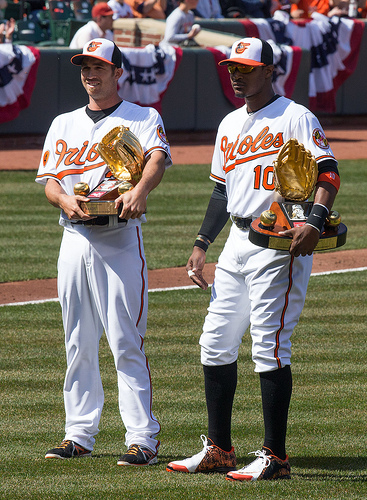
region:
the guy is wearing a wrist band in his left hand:
[164, 33, 351, 488]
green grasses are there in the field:
[12, 313, 364, 498]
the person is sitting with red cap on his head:
[67, 2, 124, 48]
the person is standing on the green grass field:
[23, 38, 173, 492]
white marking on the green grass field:
[2, 258, 362, 338]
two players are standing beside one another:
[27, 26, 356, 484]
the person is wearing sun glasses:
[163, 32, 349, 486]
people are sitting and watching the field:
[1, 2, 362, 172]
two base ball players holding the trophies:
[25, 28, 348, 481]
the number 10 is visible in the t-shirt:
[207, 103, 337, 246]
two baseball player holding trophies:
[36, 39, 347, 482]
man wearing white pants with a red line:
[56, 221, 158, 452]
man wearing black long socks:
[202, 362, 292, 462]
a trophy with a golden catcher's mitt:
[250, 142, 347, 250]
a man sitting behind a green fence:
[69, 2, 114, 48]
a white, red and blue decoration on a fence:
[117, 44, 181, 116]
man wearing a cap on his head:
[71, 38, 122, 70]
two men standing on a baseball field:
[35, 35, 345, 479]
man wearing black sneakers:
[45, 439, 157, 467]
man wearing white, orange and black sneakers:
[165, 443, 292, 480]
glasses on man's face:
[220, 62, 261, 75]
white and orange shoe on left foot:
[225, 443, 292, 487]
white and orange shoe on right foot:
[169, 440, 238, 474]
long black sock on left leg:
[262, 368, 296, 458]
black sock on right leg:
[203, 362, 238, 446]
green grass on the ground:
[303, 277, 363, 453]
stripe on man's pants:
[274, 255, 296, 368]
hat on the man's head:
[220, 37, 277, 73]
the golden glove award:
[268, 139, 320, 199]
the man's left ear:
[113, 63, 123, 82]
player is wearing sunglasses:
[214, 47, 275, 119]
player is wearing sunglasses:
[220, 54, 253, 89]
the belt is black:
[67, 209, 128, 234]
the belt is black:
[73, 209, 107, 225]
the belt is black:
[78, 215, 124, 226]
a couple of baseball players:
[34, 40, 347, 483]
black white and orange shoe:
[165, 434, 233, 470]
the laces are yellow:
[125, 444, 137, 454]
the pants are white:
[56, 226, 159, 455]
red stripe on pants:
[135, 224, 160, 456]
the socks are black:
[203, 363, 291, 460]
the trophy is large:
[250, 139, 345, 249]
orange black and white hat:
[71, 38, 122, 68]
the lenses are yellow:
[228, 63, 255, 72]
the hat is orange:
[92, 2, 118, 16]